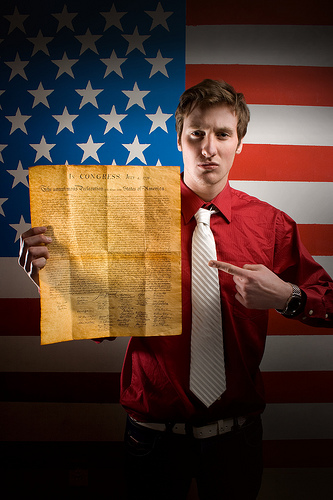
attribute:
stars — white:
[0, 0, 174, 246]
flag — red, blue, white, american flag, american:
[1, 0, 332, 499]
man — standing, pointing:
[17, 78, 332, 499]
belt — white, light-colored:
[125, 395, 265, 441]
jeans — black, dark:
[120, 412, 262, 500]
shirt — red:
[92, 171, 332, 424]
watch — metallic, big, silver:
[277, 282, 302, 320]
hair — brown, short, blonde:
[174, 78, 250, 149]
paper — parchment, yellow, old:
[28, 166, 183, 347]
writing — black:
[38, 172, 174, 331]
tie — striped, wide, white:
[189, 208, 226, 406]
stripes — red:
[0, 0, 332, 499]